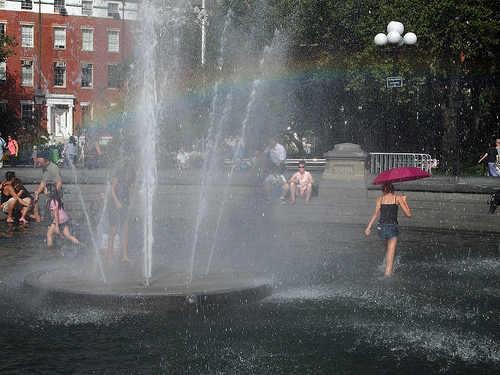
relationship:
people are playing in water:
[5, 149, 409, 278] [63, 6, 318, 284]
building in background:
[4, 3, 190, 169] [1, 6, 497, 175]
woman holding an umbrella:
[368, 185, 415, 283] [372, 161, 431, 186]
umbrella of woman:
[372, 161, 431, 186] [368, 185, 415, 283]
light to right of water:
[373, 16, 419, 138] [63, 6, 318, 284]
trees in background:
[185, 9, 499, 165] [1, 6, 497, 175]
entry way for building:
[45, 92, 74, 141] [4, 3, 190, 169]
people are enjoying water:
[5, 149, 409, 278] [63, 6, 318, 284]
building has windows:
[4, 3, 190, 169] [1, 21, 119, 95]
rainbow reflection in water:
[63, 48, 355, 153] [63, 6, 318, 284]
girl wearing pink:
[40, 184, 78, 245] [45, 200, 67, 222]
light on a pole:
[373, 16, 419, 138] [389, 55, 406, 103]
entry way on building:
[45, 92, 74, 141] [4, 3, 190, 169]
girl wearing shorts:
[40, 184, 78, 245] [55, 221, 68, 231]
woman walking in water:
[368, 185, 415, 283] [63, 6, 318, 284]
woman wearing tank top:
[368, 185, 415, 283] [375, 198, 399, 215]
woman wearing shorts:
[368, 185, 415, 283] [378, 226, 397, 239]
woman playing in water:
[368, 185, 415, 283] [63, 6, 318, 284]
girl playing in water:
[40, 184, 78, 245] [63, 6, 318, 284]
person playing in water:
[105, 160, 138, 262] [63, 6, 318, 284]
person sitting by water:
[291, 162, 311, 200] [63, 6, 318, 284]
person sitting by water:
[266, 163, 287, 200] [63, 6, 318, 284]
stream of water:
[125, 6, 162, 283] [63, 6, 318, 284]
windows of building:
[1, 21, 119, 95] [4, 3, 190, 169]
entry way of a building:
[45, 92, 74, 141] [4, 3, 190, 169]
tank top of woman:
[375, 198, 399, 215] [368, 185, 415, 283]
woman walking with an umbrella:
[368, 185, 415, 283] [372, 161, 431, 186]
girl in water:
[40, 184, 78, 245] [63, 6, 318, 284]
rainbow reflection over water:
[63, 48, 355, 153] [63, 6, 318, 284]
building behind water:
[4, 3, 190, 169] [63, 6, 318, 284]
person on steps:
[291, 162, 311, 200] [189, 179, 496, 226]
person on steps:
[266, 163, 287, 200] [189, 179, 496, 226]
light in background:
[373, 16, 419, 138] [1, 6, 497, 175]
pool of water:
[8, 228, 493, 374] [63, 6, 318, 284]